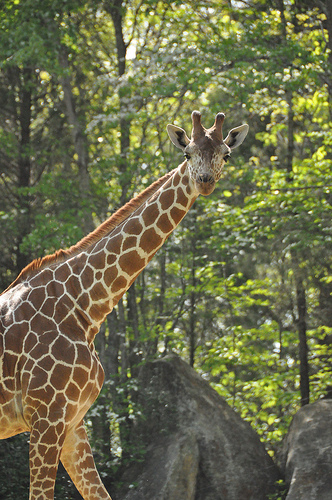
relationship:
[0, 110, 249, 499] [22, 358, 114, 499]
giraffe has front legs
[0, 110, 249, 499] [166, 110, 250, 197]
giraffe has a head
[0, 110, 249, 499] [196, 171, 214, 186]
giraffe has a nose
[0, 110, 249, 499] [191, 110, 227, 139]
giraffe has horns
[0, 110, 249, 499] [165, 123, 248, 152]
giraffe has ears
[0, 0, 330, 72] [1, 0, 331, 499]
sky visible through trees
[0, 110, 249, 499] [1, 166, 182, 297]
giraffe has a mane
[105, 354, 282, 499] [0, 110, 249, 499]
boulder near giraffe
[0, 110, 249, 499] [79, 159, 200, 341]
giraffe has a neck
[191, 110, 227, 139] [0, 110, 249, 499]
horns on giraffe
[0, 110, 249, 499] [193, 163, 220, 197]
giraffe has a muzzle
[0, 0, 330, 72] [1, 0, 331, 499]
sky behind trees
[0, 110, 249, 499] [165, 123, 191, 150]
giraffe has a right ear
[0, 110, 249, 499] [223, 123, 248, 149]
giraffe has a left ear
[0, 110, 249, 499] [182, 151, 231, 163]
giraffe has eyes